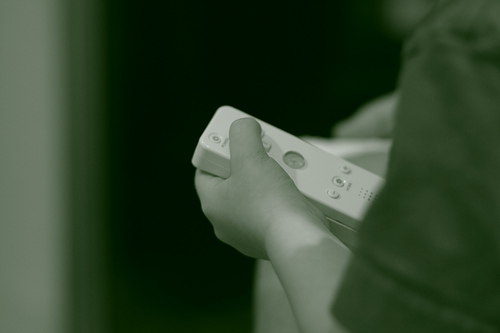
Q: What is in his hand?
A: A game controller.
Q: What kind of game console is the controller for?
A: Wii.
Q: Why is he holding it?
A: He's playing a game.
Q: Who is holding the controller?
A: A person.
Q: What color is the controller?
A: White.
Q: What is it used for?
A: Controlling a game.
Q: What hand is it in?
A: Left.